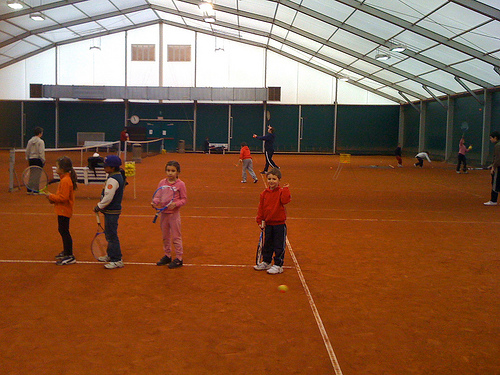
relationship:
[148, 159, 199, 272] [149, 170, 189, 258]
girl in outfit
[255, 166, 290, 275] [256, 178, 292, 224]
boy wearing shirt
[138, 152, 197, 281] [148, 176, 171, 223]
girl holding raquet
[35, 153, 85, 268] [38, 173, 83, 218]
girl wearing sweatshirt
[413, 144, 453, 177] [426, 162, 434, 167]
person bending picking up something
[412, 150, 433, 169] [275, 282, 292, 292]
child picking up tennis ball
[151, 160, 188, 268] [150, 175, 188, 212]
girl wearing sweater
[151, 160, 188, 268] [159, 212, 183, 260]
girl wearing pants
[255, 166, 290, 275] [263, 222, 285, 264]
boy wearing pants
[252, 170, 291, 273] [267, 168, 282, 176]
boy has hair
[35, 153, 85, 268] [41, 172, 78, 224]
girl wearing orange sweater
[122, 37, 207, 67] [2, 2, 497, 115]
signs on windows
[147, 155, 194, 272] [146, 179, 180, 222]
girl holding tennis racket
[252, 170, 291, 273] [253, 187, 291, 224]
boy wearing coat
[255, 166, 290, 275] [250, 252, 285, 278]
boy has shoes on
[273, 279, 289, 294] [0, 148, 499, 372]
ball on floor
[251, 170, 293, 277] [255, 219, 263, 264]
child holding tennis racket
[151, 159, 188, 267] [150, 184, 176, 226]
child holding tennis racket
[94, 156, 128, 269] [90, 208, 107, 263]
child holding tennis racket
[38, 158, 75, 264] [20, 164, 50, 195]
child holding tennis racket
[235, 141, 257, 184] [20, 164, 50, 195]
child holding tennis racket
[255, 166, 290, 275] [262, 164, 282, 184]
boy has hair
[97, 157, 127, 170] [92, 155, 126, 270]
cap on kid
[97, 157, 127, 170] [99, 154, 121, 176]
cap on head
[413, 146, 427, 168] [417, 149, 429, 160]
kid wears top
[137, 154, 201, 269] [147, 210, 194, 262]
girl wearing pants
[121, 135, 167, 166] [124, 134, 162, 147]
net with trim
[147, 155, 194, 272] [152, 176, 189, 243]
girl wearing pink shirt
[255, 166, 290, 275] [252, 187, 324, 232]
boy wearing sweater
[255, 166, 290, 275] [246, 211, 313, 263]
boy wearing sweatpants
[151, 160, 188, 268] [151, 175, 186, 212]
girl wears shirt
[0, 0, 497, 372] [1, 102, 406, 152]
building has wall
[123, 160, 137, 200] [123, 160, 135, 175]
basket has tennis balls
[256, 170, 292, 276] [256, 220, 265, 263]
kid holds racket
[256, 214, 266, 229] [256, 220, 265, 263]
hand holds racket